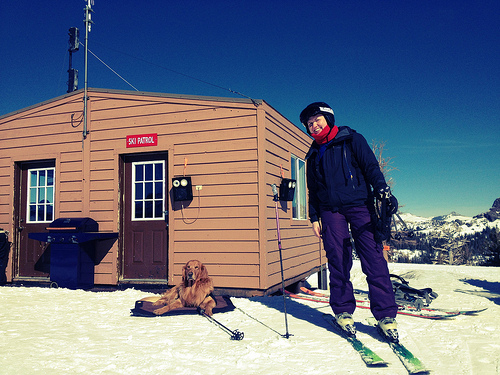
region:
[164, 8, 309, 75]
blue sky above the building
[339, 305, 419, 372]
skis on the ground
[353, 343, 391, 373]
front of the ski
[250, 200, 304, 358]
ski pole next to person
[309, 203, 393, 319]
pants on the person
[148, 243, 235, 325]
dog laying down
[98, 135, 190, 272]
door on the building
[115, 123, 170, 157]
red and white sign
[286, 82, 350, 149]
head of the person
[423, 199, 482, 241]
mountains in the background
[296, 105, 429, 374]
a person on skis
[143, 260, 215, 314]
a dog lying on the ground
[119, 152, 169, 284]
a brown door with a window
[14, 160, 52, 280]
a brown door with a window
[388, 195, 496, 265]
snow covered mountains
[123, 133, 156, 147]
a red and white sign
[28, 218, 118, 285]
a blue outdoor grill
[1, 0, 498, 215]
a clear blue sky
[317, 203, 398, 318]
a pair of purple ski pants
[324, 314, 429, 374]
a pair of green skiis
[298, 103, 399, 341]
A person standing outside in the snow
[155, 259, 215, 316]
A dog laying down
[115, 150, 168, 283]
A brown door on a building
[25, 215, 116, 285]
A barbecue grill outside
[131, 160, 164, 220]
A 9 squared window on a door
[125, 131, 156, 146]
A sign on a building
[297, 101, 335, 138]
A black helmet that is being worn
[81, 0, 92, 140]
An electric pole on a house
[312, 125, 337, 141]
A red scarf around a neck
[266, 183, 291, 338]
A purple colored skii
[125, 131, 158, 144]
ski patrol sign on building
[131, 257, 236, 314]
irish setter on ground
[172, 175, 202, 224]
Electric meter on side of building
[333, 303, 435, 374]
two skis on woman's feet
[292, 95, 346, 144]
woman's head on her neck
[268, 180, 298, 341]
pink ski pole standing up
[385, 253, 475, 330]
skis laying on the ground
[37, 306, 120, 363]
snow in front of building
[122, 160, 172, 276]
brown door on building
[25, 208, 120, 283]
black grill sitting in snow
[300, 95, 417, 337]
woman dressed in skiing attire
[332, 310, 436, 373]
woman wearing green skis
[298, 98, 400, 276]
woman leaning to the left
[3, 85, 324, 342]
a brown building sitting amidst the snow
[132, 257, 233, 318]
large dog sitting on a mat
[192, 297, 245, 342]
ski pole near dog's paw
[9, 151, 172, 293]
outdoor grill between two doors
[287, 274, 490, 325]
long skis sitting on the snow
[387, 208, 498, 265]
snow on mountains in the distance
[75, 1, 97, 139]
antennae attached to front of building